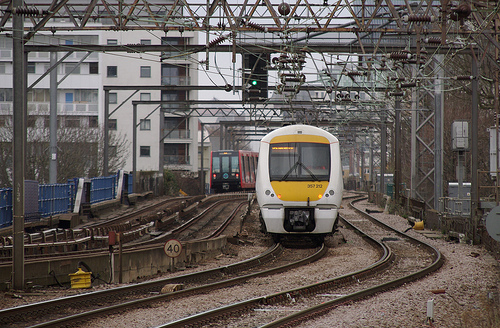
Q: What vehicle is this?
A: A train.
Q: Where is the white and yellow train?
A: On the tracks.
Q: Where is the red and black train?
A: Behind the white and yellow one.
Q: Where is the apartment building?
A: Left from trains.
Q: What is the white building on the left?
A: Apartment building.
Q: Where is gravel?
A: Between and next to tracks.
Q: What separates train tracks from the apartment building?
A: Blue fence.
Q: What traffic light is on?
A: Green.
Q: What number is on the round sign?
A: 40.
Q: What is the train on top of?
A: Tracks.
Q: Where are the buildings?
A: Behind tracks.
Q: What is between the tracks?
A: Gravel.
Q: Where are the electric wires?
A: Above train.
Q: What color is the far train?
A: Red.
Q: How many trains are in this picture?
A: Two.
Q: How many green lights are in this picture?
A: One.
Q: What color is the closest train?
A: White.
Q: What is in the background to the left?
A: A building.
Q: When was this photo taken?
A: During the daytime.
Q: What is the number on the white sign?
A: 40.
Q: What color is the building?
A: White.